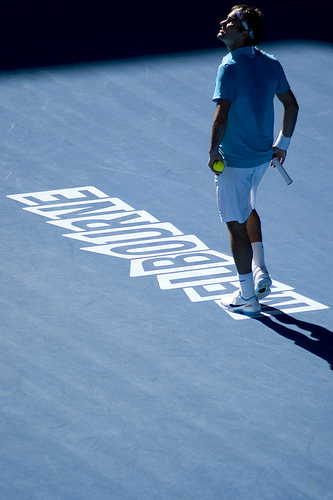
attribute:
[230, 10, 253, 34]
sweatband — White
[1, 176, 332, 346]
letters — white, blocks, MELBOURNE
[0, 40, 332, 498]
court — blue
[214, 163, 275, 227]
shorts. — white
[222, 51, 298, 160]
shirt — blue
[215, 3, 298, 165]
shirt — blue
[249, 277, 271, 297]
shoe — edge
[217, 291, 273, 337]
shoe — part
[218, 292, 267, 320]
shoe — white, Nike, tennis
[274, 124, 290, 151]
band — white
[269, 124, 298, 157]
wrist — mans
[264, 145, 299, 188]
handle — white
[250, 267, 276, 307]
shoe — White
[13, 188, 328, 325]
letters — white, Blue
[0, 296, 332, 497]
floor — Blue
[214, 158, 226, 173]
ball — yellow, tennis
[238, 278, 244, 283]
sock — part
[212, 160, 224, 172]
ball — bright green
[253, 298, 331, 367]
shadow — Black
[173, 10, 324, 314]
player — tennis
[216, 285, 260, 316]
shoe — white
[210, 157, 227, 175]
ball — green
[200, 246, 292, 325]
shoes — white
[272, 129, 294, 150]
wristband — white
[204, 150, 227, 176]
hand — man's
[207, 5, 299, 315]
tennis player — Male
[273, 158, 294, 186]
grip — white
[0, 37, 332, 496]
tarp — blue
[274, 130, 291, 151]
sweatband — White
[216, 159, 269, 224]
shorts — white 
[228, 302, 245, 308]
swoosh — Black, Nike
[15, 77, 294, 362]
court — edge